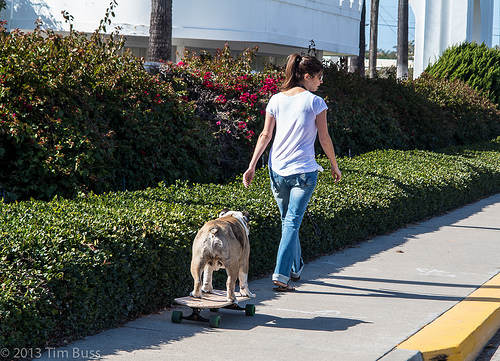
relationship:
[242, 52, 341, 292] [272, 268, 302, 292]
girl wearing sandals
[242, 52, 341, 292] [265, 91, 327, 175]
girl wearing shirt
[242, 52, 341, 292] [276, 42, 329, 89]
girl has brown hair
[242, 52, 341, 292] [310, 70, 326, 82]
girl wearing glasses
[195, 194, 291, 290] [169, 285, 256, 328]
dog riding skateboard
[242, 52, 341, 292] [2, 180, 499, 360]
girl on pavement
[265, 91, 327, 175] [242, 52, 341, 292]
shirt on girl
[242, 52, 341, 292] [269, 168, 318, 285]
girl wearing jeans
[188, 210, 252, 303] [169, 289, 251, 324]
dog on skateboard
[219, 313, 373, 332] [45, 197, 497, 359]
shadow on pavement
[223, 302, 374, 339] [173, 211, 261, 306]
shadow of dog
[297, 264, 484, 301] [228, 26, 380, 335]
shadow of girl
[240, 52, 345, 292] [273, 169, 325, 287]
girl wearing jeans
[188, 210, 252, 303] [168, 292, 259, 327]
dog on a skateboard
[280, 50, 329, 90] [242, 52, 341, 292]
hair on a girl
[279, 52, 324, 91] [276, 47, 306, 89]
hair in a ponytail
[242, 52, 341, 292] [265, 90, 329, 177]
girl wearing a shirt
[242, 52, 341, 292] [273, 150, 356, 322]
girl wearing jeans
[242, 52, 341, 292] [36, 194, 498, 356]
girl walking down sidewalk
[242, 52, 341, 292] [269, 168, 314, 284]
girl dressed in jeans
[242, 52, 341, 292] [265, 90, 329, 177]
girl dressed in shirt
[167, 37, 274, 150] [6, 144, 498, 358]
flowers in a bush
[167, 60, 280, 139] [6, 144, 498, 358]
flowers in a bush